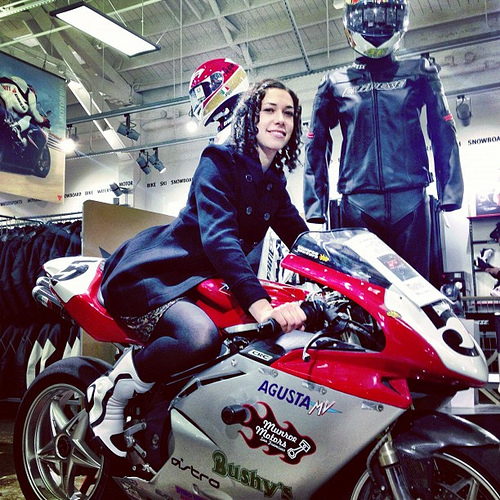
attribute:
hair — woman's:
[233, 79, 301, 171]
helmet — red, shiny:
[186, 49, 235, 139]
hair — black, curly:
[222, 85, 317, 173]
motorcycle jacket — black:
[303, 56, 466, 232]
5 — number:
[421, 290, 486, 368]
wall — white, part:
[7, 17, 499, 292]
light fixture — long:
[41, 2, 163, 62]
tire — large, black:
[316, 418, 491, 498]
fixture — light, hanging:
[54, 9, 159, 61]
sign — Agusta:
[221, 396, 314, 468]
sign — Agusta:
[258, 376, 335, 414]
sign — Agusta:
[210, 448, 292, 498]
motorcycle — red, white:
[57, 256, 487, 498]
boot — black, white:
[78, 337, 158, 462]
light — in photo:
[62, 120, 167, 179]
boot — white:
[84, 345, 154, 463]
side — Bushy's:
[194, 366, 309, 497]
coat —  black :
[100, 135, 311, 315]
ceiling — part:
[0, 0, 499, 128]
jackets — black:
[4, 327, 21, 442]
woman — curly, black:
[82, 78, 307, 470]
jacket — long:
[103, 133, 300, 320]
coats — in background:
[3, 223, 80, 400]